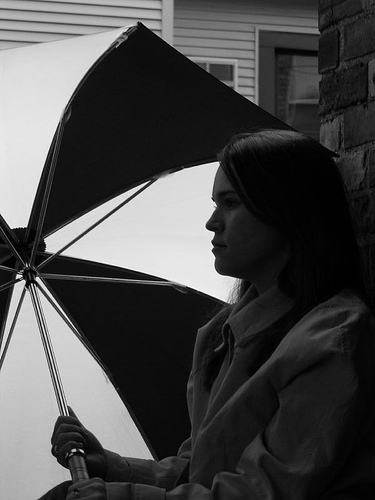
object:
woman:
[41, 129, 374, 499]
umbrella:
[0, 20, 336, 497]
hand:
[48, 408, 111, 484]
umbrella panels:
[36, 27, 335, 232]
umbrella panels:
[40, 163, 271, 302]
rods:
[21, 264, 99, 494]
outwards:
[0, 21, 347, 145]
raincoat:
[105, 285, 362, 500]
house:
[1, 6, 370, 111]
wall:
[314, 8, 373, 217]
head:
[205, 129, 349, 291]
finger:
[48, 431, 82, 448]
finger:
[54, 442, 82, 465]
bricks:
[317, 12, 372, 71]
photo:
[0, 6, 375, 499]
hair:
[217, 129, 359, 369]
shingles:
[1, 0, 304, 26]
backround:
[4, 9, 372, 152]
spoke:
[36, 271, 189, 293]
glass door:
[263, 27, 337, 150]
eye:
[223, 198, 238, 209]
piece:
[0, 227, 44, 277]